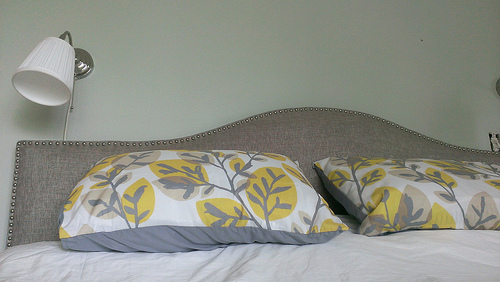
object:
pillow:
[57, 149, 350, 253]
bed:
[0, 106, 500, 282]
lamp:
[10, 30, 94, 107]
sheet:
[0, 214, 500, 282]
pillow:
[312, 156, 500, 238]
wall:
[0, 0, 500, 251]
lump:
[184, 244, 230, 282]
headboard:
[5, 106, 500, 247]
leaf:
[123, 204, 135, 215]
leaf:
[361, 177, 368, 184]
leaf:
[269, 186, 293, 195]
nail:
[17, 142, 21, 146]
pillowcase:
[56, 149, 350, 254]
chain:
[69, 75, 74, 113]